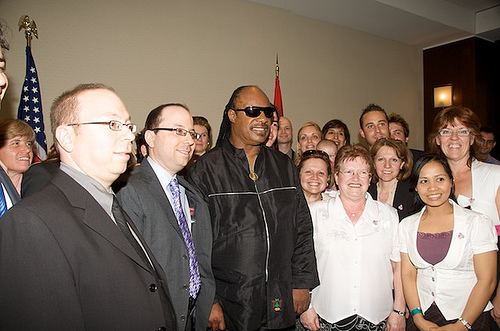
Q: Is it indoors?
A: Yes, it is indoors.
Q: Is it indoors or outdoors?
A: It is indoors.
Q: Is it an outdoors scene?
A: No, it is indoors.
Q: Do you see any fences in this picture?
A: No, there are no fences.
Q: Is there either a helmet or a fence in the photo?
A: No, there are no fences or helmets.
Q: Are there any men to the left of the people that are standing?
A: Yes, there is a man to the left of the people.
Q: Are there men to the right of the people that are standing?
A: No, the man is to the left of the people.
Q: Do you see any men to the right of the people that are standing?
A: No, the man is to the left of the people.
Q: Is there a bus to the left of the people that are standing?
A: No, there is a man to the left of the people.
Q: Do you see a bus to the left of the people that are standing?
A: No, there is a man to the left of the people.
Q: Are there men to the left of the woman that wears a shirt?
A: Yes, there is a man to the left of the woman.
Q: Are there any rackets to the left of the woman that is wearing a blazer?
A: No, there is a man to the left of the woman.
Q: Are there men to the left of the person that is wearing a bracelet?
A: Yes, there is a man to the left of the person.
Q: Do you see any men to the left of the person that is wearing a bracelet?
A: Yes, there is a man to the left of the person.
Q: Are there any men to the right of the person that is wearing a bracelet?
A: No, the man is to the left of the person.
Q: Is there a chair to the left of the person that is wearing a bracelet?
A: No, there is a man to the left of the person.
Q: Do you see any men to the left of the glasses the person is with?
A: Yes, there is a man to the left of the glasses.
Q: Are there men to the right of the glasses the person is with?
A: No, the man is to the left of the glasses.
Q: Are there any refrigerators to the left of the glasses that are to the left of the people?
A: No, there is a man to the left of the glasses.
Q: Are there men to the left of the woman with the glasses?
A: Yes, there is a man to the left of the woman.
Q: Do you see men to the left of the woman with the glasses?
A: Yes, there is a man to the left of the woman.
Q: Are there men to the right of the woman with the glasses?
A: No, the man is to the left of the woman.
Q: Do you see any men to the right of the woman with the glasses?
A: No, the man is to the left of the woman.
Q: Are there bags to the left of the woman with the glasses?
A: No, there is a man to the left of the woman.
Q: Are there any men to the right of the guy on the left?
A: Yes, there is a man to the right of the guy.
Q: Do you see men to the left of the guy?
A: No, the man is to the right of the guy.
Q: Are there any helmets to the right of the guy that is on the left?
A: No, there is a man to the right of the guy.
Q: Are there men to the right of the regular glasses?
A: Yes, there is a man to the right of the glasses.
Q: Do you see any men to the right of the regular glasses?
A: Yes, there is a man to the right of the glasses.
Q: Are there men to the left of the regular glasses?
A: No, the man is to the right of the glasses.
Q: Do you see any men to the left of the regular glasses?
A: No, the man is to the right of the glasses.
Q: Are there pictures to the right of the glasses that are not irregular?
A: No, there is a man to the right of the glasses.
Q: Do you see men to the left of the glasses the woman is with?
A: Yes, there is a man to the left of the glasses.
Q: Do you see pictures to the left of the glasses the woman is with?
A: No, there is a man to the left of the glasses.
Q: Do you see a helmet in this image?
A: No, there are no helmets.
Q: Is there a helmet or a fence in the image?
A: No, there are no helmets or fences.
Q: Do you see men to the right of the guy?
A: Yes, there is a man to the right of the guy.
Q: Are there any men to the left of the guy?
A: No, the man is to the right of the guy.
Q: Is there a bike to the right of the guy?
A: No, there is a man to the right of the guy.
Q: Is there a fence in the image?
A: No, there are no fences.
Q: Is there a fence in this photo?
A: No, there are no fences.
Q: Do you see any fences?
A: No, there are no fences.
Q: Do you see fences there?
A: No, there are no fences.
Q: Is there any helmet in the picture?
A: No, there are no helmets.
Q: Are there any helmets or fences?
A: No, there are no helmets or fences.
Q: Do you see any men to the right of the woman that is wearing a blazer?
A: Yes, there is a man to the right of the woman.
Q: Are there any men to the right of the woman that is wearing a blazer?
A: Yes, there is a man to the right of the woman.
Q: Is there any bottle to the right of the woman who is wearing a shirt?
A: No, there is a man to the right of the woman.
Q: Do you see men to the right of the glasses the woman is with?
A: Yes, there is a man to the right of the glasses.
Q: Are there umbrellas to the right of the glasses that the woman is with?
A: No, there is a man to the right of the glasses.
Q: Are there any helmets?
A: No, there are no helmets.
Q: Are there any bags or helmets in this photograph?
A: No, there are no helmets or bags.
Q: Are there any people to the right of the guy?
A: Yes, there is a person to the right of the guy.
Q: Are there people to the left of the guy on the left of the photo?
A: No, the person is to the right of the guy.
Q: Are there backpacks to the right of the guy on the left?
A: No, there is a person to the right of the guy.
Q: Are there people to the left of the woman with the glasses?
A: Yes, there is a person to the left of the woman.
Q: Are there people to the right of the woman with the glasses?
A: No, the person is to the left of the woman.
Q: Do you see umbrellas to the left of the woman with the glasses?
A: No, there is a person to the left of the woman.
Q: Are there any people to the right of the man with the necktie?
A: Yes, there is a person to the right of the man.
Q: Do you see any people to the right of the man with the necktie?
A: Yes, there is a person to the right of the man.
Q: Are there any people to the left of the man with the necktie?
A: No, the person is to the right of the man.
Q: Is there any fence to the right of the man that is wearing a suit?
A: No, there is a person to the right of the man.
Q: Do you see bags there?
A: No, there are no bags.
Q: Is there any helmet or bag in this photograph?
A: No, there are no bags or helmets.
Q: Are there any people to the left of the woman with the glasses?
A: Yes, there is a person to the left of the woman.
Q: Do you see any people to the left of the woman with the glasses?
A: Yes, there is a person to the left of the woman.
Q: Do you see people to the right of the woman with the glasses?
A: No, the person is to the left of the woman.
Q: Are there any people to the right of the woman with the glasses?
A: No, the person is to the left of the woman.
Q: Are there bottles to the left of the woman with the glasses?
A: No, there is a person to the left of the woman.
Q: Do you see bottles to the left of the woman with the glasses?
A: No, there is a person to the left of the woman.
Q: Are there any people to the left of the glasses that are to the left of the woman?
A: Yes, there is a person to the left of the glasses.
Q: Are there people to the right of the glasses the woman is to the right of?
A: No, the person is to the left of the glasses.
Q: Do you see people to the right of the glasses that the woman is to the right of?
A: No, the person is to the left of the glasses.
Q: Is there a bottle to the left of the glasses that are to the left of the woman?
A: No, there is a person to the left of the glasses.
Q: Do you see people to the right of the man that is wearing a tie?
A: Yes, there is a person to the right of the man.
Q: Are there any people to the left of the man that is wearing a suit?
A: No, the person is to the right of the man.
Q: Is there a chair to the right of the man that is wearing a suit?
A: No, there is a person to the right of the man.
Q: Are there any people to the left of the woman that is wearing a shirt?
A: Yes, there is a person to the left of the woman.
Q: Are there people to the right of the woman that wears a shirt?
A: No, the person is to the left of the woman.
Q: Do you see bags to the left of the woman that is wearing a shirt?
A: No, there is a person to the left of the woman.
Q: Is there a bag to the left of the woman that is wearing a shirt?
A: No, there is a person to the left of the woman.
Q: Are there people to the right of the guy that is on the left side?
A: Yes, there is a person to the right of the guy.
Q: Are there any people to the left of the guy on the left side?
A: No, the person is to the right of the guy.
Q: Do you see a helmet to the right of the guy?
A: No, there is a person to the right of the guy.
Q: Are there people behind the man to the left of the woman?
A: Yes, there is a person behind the man.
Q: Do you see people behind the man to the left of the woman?
A: Yes, there is a person behind the man.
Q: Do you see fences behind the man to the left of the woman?
A: No, there is a person behind the man.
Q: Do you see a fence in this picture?
A: No, there are no fences.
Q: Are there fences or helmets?
A: No, there are no fences or helmets.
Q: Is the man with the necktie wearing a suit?
A: Yes, the man is wearing a suit.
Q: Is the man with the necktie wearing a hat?
A: No, the man is wearing a suit.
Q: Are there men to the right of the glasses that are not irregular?
A: Yes, there is a man to the right of the glasses.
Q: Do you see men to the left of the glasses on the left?
A: No, the man is to the right of the glasses.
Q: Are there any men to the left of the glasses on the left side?
A: No, the man is to the right of the glasses.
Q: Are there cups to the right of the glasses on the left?
A: No, there is a man to the right of the glasses.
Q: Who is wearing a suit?
A: The man is wearing a suit.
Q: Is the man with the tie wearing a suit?
A: Yes, the man is wearing a suit.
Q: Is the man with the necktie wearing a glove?
A: No, the man is wearing a suit.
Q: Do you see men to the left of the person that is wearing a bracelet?
A: Yes, there is a man to the left of the person.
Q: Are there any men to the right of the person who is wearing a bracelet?
A: No, the man is to the left of the person.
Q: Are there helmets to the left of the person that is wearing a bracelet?
A: No, there is a man to the left of the person.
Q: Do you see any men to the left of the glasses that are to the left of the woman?
A: Yes, there is a man to the left of the glasses.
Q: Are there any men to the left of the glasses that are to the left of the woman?
A: Yes, there is a man to the left of the glasses.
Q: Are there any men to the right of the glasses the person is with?
A: No, the man is to the left of the glasses.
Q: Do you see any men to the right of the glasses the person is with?
A: No, the man is to the left of the glasses.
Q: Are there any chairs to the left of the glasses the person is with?
A: No, there is a man to the left of the glasses.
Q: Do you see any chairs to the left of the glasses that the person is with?
A: No, there is a man to the left of the glasses.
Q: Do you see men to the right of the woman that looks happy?
A: Yes, there is a man to the right of the woman.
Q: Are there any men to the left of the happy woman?
A: No, the man is to the right of the woman.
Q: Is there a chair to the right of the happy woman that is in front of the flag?
A: No, there is a man to the right of the woman.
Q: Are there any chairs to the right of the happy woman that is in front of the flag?
A: No, there is a man to the right of the woman.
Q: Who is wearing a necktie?
A: The man is wearing a necktie.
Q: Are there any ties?
A: Yes, there is a tie.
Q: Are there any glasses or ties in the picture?
A: Yes, there is a tie.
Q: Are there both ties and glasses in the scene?
A: Yes, there are both a tie and glasses.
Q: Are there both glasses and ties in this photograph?
A: Yes, there are both a tie and glasses.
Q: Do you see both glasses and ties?
A: Yes, there are both a tie and glasses.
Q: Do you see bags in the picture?
A: No, there are no bags.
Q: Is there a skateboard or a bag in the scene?
A: No, there are no bags or skateboards.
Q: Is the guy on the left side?
A: Yes, the guy is on the left of the image.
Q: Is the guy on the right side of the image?
A: No, the guy is on the left of the image.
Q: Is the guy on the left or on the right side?
A: The guy is on the left of the image.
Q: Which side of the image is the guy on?
A: The guy is on the left of the image.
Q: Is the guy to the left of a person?
A: Yes, the guy is to the left of a person.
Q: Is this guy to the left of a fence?
A: No, the guy is to the left of a person.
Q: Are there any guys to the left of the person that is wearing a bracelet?
A: Yes, there is a guy to the left of the person.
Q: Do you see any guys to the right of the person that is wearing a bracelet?
A: No, the guy is to the left of the person.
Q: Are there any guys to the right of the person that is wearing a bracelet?
A: No, the guy is to the left of the person.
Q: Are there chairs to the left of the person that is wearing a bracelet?
A: No, there is a guy to the left of the person.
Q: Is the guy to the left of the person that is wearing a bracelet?
A: Yes, the guy is to the left of the person.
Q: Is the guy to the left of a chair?
A: No, the guy is to the left of the person.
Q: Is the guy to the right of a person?
A: No, the guy is to the left of a person.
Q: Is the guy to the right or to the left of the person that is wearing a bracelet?
A: The guy is to the left of the person.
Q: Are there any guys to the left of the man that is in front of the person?
A: Yes, there is a guy to the left of the man.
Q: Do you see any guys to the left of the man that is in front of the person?
A: Yes, there is a guy to the left of the man.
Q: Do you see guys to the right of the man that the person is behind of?
A: No, the guy is to the left of the man.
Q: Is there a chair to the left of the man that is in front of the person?
A: No, there is a guy to the left of the man.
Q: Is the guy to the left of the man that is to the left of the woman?
A: Yes, the guy is to the left of the man.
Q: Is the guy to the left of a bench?
A: No, the guy is to the left of the man.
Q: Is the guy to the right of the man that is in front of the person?
A: No, the guy is to the left of the man.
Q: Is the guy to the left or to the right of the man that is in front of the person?
A: The guy is to the left of the man.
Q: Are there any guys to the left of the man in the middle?
A: Yes, there is a guy to the left of the man.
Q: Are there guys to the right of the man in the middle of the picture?
A: No, the guy is to the left of the man.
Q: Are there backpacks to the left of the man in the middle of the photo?
A: No, there is a guy to the left of the man.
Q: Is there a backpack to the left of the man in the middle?
A: No, there is a guy to the left of the man.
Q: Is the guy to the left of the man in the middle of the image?
A: Yes, the guy is to the left of the man.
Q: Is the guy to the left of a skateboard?
A: No, the guy is to the left of the man.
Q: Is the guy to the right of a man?
A: No, the guy is to the left of a man.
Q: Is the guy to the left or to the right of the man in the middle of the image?
A: The guy is to the left of the man.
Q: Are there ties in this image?
A: Yes, there is a tie.